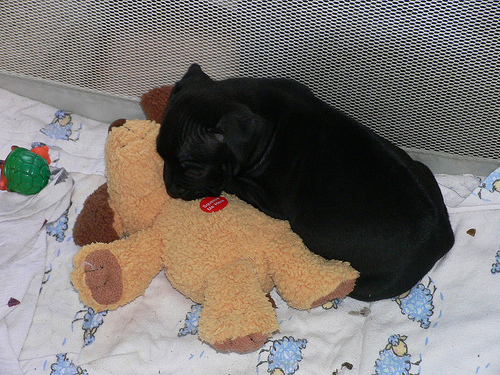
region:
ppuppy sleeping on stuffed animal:
[93, 58, 450, 340]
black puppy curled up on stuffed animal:
[146, 56, 456, 305]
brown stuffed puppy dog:
[58, 99, 351, 341]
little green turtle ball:
[8, 136, 58, 206]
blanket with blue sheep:
[63, 308, 340, 373]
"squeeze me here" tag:
[196, 181, 233, 220]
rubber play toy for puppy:
[5, 128, 57, 203]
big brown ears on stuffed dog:
[52, 106, 142, 274]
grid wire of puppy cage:
[28, 8, 495, 179]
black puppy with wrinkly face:
[149, 53, 248, 215]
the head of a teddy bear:
[68, 98, 193, 250]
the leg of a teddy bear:
[188, 261, 282, 346]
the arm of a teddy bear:
[116, 217, 159, 308]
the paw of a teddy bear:
[65, 232, 127, 319]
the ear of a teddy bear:
[68, 172, 120, 250]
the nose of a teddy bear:
[105, 111, 133, 136]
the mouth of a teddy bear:
[117, 120, 160, 153]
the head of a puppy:
[141, 53, 271, 209]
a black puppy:
[147, 50, 463, 310]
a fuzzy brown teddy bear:
[52, 77, 380, 359]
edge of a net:
[113, 81, 116, 88]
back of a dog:
[321, 138, 358, 175]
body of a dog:
[321, 231, 328, 271]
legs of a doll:
[232, 302, 252, 334]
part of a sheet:
[29, 229, 30, 268]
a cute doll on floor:
[73, 122, 332, 356]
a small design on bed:
[379, 324, 413, 369]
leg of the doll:
[188, 277, 303, 369]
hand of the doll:
[71, 237, 157, 317]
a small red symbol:
[191, 187, 241, 216]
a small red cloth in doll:
[201, 172, 229, 231]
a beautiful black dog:
[138, 62, 481, 285]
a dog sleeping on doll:
[49, 49, 499, 348]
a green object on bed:
[2, 132, 62, 216]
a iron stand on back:
[88, 1, 498, 120]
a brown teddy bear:
[63, 73, 367, 360]